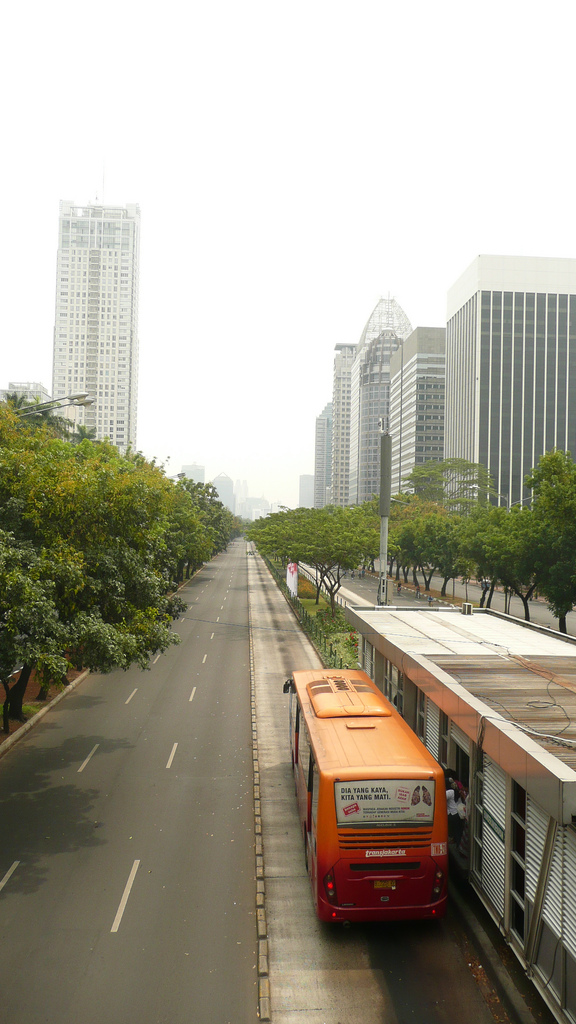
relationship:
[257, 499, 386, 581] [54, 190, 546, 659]
trees in an urban area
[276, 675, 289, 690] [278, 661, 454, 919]
mirror of a bus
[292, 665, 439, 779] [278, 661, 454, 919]
roof of bus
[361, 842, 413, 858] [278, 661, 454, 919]
writing on bus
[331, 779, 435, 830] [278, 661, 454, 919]
ad on bus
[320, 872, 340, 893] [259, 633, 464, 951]
tail light on bus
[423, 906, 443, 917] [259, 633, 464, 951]
tail light on bus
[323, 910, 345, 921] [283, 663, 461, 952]
tail light on bus